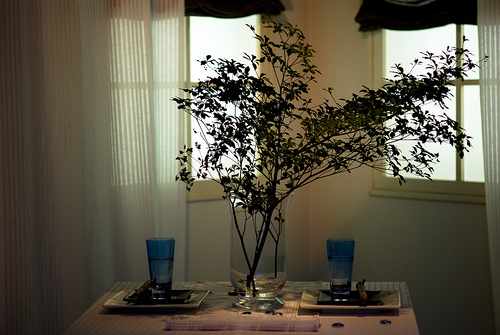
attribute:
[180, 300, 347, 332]
napkins — cloth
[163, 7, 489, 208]
plant — green, brown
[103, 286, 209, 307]
plate — square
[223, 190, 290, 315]
vase — large, clear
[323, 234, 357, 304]
glass — blue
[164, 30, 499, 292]
tree — backlit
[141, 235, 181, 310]
cup — blue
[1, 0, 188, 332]
curtain — long, white, see through, sheer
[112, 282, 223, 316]
plate — square, white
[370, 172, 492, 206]
window sill — wooden, white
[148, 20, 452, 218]
limbs — thin, small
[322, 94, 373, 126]
leaves — small, green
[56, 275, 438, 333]
table — small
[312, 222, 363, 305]
glass — clear, blue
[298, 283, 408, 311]
plate — white, square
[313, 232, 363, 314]
vase — large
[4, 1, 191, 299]
curtain — white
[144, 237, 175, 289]
glass — blue, clear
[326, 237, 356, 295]
glass — blue, clear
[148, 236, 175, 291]
glass — clear, blue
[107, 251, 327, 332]
table — small